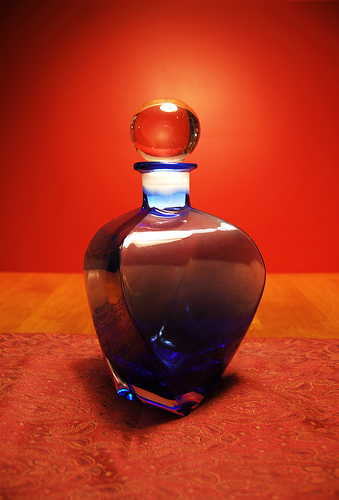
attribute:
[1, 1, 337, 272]
wall — red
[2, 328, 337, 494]
cloth — dark red, red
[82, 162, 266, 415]
vase — blue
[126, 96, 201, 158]
glass top — clear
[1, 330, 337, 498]
print — gold, red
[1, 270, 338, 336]
table — wooden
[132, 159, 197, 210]
bottle neck — dark blue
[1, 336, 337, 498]
tablecloth — red